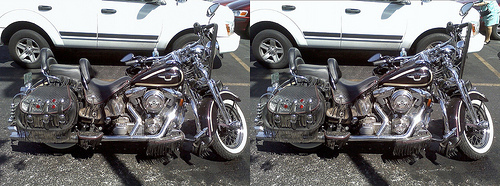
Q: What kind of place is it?
A: It is a pavement.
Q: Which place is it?
A: It is a pavement.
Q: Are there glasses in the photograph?
A: No, there are no glasses.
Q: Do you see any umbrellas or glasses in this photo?
A: No, there are no glasses or umbrellas.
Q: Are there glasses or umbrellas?
A: No, there are no glasses or umbrellas.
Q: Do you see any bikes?
A: Yes, there is a bike.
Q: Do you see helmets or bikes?
A: Yes, there is a bike.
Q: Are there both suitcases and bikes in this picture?
A: No, there is a bike but no suitcases.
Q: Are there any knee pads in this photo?
A: No, there are no knee pads.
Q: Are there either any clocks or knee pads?
A: No, there are no knee pads or clocks.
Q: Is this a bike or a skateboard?
A: This is a bike.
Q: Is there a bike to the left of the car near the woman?
A: Yes, there is a bike to the left of the car.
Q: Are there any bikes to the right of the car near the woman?
A: No, the bike is to the left of the car.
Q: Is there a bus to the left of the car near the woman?
A: No, there is a bike to the left of the car.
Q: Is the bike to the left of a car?
A: Yes, the bike is to the left of a car.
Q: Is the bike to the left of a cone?
A: No, the bike is to the left of a car.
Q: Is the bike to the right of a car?
A: No, the bike is to the left of a car.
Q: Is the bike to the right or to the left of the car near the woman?
A: The bike is to the left of the car.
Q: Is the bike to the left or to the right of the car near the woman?
A: The bike is to the left of the car.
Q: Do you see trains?
A: No, there are no trains.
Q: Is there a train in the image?
A: No, there are no trains.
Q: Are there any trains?
A: No, there are no trains.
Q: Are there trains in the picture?
A: No, there are no trains.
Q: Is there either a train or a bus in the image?
A: No, there are no trains or buses.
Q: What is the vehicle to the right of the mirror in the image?
A: The vehicle is a car.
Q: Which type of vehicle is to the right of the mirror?
A: The vehicle is a car.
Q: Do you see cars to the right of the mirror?
A: Yes, there is a car to the right of the mirror.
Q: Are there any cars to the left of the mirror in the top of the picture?
A: No, the car is to the right of the mirror.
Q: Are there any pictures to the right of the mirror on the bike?
A: No, there is a car to the right of the mirror.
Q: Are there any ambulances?
A: No, there are no ambulances.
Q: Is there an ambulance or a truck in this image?
A: No, there are no ambulances or trucks.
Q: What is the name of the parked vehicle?
A: The vehicle is a car.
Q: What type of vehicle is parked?
A: The vehicle is a car.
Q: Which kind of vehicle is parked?
A: The vehicle is a car.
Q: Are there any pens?
A: No, there are no pens.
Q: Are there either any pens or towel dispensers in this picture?
A: No, there are no pens or towel dispensers.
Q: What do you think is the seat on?
A: The seat is on the bike.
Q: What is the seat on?
A: The seat is on the bike.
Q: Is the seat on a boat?
A: No, the seat is on the bike.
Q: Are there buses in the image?
A: No, there are no buses.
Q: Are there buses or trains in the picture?
A: No, there are no buses or trains.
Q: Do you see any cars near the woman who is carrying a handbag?
A: Yes, there is a car near the woman.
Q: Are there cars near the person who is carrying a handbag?
A: Yes, there is a car near the woman.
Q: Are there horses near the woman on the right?
A: No, there is a car near the woman.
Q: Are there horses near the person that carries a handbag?
A: No, there is a car near the woman.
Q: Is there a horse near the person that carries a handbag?
A: No, there is a car near the woman.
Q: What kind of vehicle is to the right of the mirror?
A: The vehicle is a car.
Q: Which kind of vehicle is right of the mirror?
A: The vehicle is a car.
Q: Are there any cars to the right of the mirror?
A: Yes, there is a car to the right of the mirror.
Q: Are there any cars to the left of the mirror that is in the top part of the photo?
A: No, the car is to the right of the mirror.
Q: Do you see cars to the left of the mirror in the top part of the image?
A: No, the car is to the right of the mirror.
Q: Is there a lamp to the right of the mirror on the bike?
A: No, there is a car to the right of the mirror.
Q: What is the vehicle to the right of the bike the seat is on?
A: The vehicle is a car.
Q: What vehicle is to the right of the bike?
A: The vehicle is a car.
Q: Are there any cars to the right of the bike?
A: Yes, there is a car to the right of the bike.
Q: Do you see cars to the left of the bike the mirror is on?
A: No, the car is to the right of the bike.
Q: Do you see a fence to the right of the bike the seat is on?
A: No, there is a car to the right of the bike.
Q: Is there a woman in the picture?
A: Yes, there is a woman.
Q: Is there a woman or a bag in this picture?
A: Yes, there is a woman.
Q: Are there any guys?
A: No, there are no guys.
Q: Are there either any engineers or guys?
A: No, there are no guys or engineers.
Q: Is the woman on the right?
A: Yes, the woman is on the right of the image.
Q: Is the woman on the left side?
A: No, the woman is on the right of the image.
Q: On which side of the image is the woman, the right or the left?
A: The woman is on the right of the image.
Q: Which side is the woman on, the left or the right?
A: The woman is on the right of the image.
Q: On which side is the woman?
A: The woman is on the right of the image.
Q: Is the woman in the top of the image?
A: Yes, the woman is in the top of the image.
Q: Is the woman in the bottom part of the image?
A: No, the woman is in the top of the image.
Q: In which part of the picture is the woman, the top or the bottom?
A: The woman is in the top of the image.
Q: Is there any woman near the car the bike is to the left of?
A: Yes, there is a woman near the car.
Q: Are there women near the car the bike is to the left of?
A: Yes, there is a woman near the car.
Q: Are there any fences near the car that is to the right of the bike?
A: No, there is a woman near the car.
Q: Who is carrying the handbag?
A: The woman is carrying the handbag.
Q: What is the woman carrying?
A: The woman is carrying a handbag.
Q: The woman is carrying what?
A: The woman is carrying a handbag.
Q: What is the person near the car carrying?
A: The woman is carrying a handbag.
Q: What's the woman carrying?
A: The woman is carrying a handbag.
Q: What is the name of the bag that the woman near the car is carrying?
A: The bag is a handbag.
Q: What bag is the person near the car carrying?
A: The woman is carrying a handbag.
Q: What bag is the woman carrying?
A: The woman is carrying a handbag.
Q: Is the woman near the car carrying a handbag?
A: Yes, the woman is carrying a handbag.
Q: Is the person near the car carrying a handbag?
A: Yes, the woman is carrying a handbag.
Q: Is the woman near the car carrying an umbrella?
A: No, the woman is carrying a handbag.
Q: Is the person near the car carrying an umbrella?
A: No, the woman is carrying a handbag.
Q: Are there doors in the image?
A: Yes, there is a door.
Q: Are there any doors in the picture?
A: Yes, there is a door.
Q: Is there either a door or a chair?
A: Yes, there is a door.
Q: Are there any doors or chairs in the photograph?
A: Yes, there is a door.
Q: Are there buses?
A: No, there are no buses.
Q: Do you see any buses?
A: No, there are no buses.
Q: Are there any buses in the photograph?
A: No, there are no buses.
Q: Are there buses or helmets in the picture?
A: No, there are no buses or helmets.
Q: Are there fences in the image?
A: No, there are no fences.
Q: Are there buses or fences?
A: No, there are no fences or buses.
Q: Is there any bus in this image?
A: No, there are no buses.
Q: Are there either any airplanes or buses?
A: No, there are no buses or airplanes.